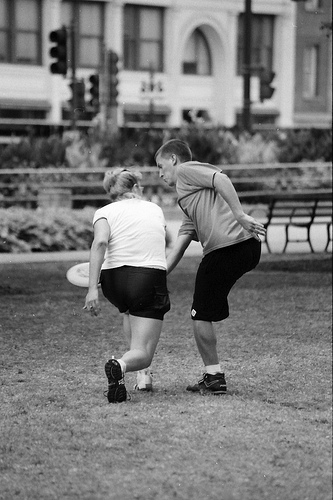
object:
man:
[152, 138, 271, 393]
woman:
[87, 163, 173, 404]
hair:
[103, 166, 139, 196]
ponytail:
[104, 162, 127, 189]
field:
[4, 257, 326, 499]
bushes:
[4, 130, 329, 167]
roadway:
[6, 118, 325, 164]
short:
[101, 269, 172, 318]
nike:
[200, 380, 223, 393]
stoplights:
[64, 26, 87, 113]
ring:
[88, 305, 95, 310]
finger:
[87, 303, 95, 316]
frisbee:
[67, 258, 102, 288]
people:
[84, 135, 266, 401]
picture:
[4, 8, 327, 492]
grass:
[6, 404, 327, 493]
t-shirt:
[178, 164, 255, 252]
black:
[190, 238, 262, 323]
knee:
[130, 340, 154, 371]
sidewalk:
[266, 199, 331, 250]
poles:
[237, 2, 256, 132]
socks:
[206, 364, 220, 374]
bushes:
[2, 206, 90, 252]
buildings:
[7, 5, 328, 137]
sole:
[106, 360, 126, 401]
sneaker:
[104, 356, 127, 404]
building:
[5, 6, 293, 137]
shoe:
[184, 375, 233, 397]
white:
[67, 266, 87, 282]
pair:
[97, 269, 171, 319]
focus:
[43, 21, 282, 122]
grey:
[175, 160, 264, 238]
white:
[111, 202, 160, 265]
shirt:
[93, 198, 168, 269]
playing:
[67, 136, 264, 409]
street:
[4, 121, 320, 138]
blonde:
[103, 165, 143, 201]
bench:
[266, 194, 332, 256]